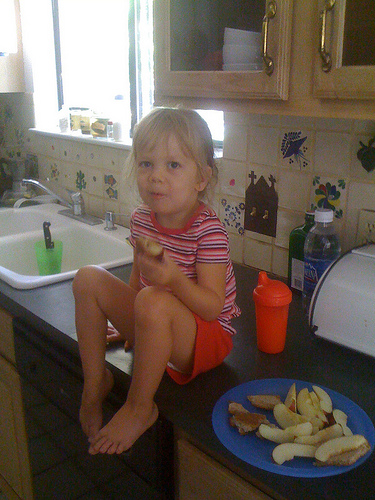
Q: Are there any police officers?
A: No, there are no police officers.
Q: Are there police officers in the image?
A: No, there are no police officers.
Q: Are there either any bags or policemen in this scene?
A: No, there are no policemen or bags.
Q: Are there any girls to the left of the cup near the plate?
A: Yes, there is a girl to the left of the cup.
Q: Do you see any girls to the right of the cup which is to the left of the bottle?
A: No, the girl is to the left of the cup.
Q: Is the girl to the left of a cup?
A: Yes, the girl is to the left of a cup.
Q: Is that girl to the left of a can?
A: No, the girl is to the left of a cup.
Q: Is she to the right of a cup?
A: No, the girl is to the left of a cup.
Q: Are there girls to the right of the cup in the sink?
A: Yes, there is a girl to the right of the cup.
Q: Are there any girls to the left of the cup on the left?
A: No, the girl is to the right of the cup.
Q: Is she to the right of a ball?
A: No, the girl is to the right of the cup.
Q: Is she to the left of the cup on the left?
A: No, the girl is to the right of the cup.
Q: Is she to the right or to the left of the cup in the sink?
A: The girl is to the right of the cup.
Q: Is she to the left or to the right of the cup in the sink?
A: The girl is to the right of the cup.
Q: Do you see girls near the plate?
A: Yes, there is a girl near the plate.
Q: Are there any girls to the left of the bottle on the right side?
A: Yes, there is a girl to the left of the bottle.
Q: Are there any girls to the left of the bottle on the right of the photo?
A: Yes, there is a girl to the left of the bottle.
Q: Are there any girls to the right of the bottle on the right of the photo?
A: No, the girl is to the left of the bottle.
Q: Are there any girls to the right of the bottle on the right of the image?
A: No, the girl is to the left of the bottle.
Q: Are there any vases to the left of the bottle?
A: No, there is a girl to the left of the bottle.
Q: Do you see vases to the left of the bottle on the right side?
A: No, there is a girl to the left of the bottle.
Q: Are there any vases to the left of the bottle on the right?
A: No, there is a girl to the left of the bottle.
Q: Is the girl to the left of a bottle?
A: Yes, the girl is to the left of a bottle.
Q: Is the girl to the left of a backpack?
A: No, the girl is to the left of a bottle.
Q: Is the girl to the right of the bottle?
A: No, the girl is to the left of the bottle.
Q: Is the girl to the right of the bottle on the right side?
A: No, the girl is to the left of the bottle.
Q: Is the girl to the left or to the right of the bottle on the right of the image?
A: The girl is to the left of the bottle.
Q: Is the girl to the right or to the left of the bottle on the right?
A: The girl is to the left of the bottle.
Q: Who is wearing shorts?
A: The girl is wearing shorts.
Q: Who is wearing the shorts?
A: The girl is wearing shorts.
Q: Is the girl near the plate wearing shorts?
A: Yes, the girl is wearing shorts.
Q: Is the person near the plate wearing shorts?
A: Yes, the girl is wearing shorts.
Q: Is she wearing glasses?
A: No, the girl is wearing shorts.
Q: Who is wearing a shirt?
A: The girl is wearing a shirt.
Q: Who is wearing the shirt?
A: The girl is wearing a shirt.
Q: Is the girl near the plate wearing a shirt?
A: Yes, the girl is wearing a shirt.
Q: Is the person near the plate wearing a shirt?
A: Yes, the girl is wearing a shirt.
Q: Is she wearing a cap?
A: No, the girl is wearing a shirt.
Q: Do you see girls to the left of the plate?
A: Yes, there is a girl to the left of the plate.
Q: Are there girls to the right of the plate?
A: No, the girl is to the left of the plate.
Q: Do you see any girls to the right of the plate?
A: No, the girl is to the left of the plate.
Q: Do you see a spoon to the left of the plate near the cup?
A: No, there is a girl to the left of the plate.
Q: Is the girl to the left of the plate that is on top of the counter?
A: Yes, the girl is to the left of the plate.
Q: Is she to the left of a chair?
A: No, the girl is to the left of the plate.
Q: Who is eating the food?
A: The girl is eating the food.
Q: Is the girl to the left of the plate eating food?
A: Yes, the girl is eating food.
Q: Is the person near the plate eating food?
A: Yes, the girl is eating food.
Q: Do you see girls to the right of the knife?
A: Yes, there is a girl to the right of the knife.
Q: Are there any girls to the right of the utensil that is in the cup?
A: Yes, there is a girl to the right of the knife.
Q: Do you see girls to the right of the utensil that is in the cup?
A: Yes, there is a girl to the right of the knife.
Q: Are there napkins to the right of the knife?
A: No, there is a girl to the right of the knife.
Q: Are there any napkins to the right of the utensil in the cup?
A: No, there is a girl to the right of the knife.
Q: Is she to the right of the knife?
A: Yes, the girl is to the right of the knife.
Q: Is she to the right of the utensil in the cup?
A: Yes, the girl is to the right of the knife.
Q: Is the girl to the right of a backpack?
A: No, the girl is to the right of the knife.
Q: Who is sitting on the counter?
A: The girl is sitting on the counter.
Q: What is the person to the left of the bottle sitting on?
A: The girl is sitting on the counter.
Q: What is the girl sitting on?
A: The girl is sitting on the counter.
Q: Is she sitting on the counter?
A: Yes, the girl is sitting on the counter.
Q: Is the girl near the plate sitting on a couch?
A: No, the girl is sitting on the counter.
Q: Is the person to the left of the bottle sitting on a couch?
A: No, the girl is sitting on the counter.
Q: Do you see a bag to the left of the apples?
A: No, there is a girl to the left of the apples.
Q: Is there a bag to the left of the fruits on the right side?
A: No, there is a girl to the left of the apples.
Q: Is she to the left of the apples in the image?
A: Yes, the girl is to the left of the apples.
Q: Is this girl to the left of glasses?
A: No, the girl is to the left of the apples.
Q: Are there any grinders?
A: No, there are no grinders.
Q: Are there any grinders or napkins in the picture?
A: No, there are no grinders or napkins.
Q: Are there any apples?
A: Yes, there are apples.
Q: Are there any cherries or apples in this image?
A: Yes, there are apples.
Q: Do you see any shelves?
A: No, there are no shelves.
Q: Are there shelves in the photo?
A: No, there are no shelves.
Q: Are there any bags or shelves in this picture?
A: No, there are no shelves or bags.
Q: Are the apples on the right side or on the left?
A: The apples are on the right of the image.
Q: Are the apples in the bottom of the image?
A: Yes, the apples are in the bottom of the image.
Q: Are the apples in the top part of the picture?
A: No, the apples are in the bottom of the image.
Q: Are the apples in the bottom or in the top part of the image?
A: The apples are in the bottom of the image.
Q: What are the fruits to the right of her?
A: The fruits are apples.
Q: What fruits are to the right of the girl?
A: The fruits are apples.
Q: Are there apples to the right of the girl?
A: Yes, there are apples to the right of the girl.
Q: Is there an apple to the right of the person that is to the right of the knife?
A: Yes, there are apples to the right of the girl.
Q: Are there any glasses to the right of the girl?
A: No, there are apples to the right of the girl.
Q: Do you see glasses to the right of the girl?
A: No, there are apples to the right of the girl.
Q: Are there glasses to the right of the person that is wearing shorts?
A: No, there are apples to the right of the girl.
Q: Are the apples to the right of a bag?
A: No, the apples are to the right of the girl.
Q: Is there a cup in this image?
A: Yes, there is a cup.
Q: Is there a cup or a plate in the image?
A: Yes, there is a cup.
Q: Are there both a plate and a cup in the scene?
A: Yes, there are both a cup and a plate.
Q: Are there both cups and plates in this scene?
A: Yes, there are both a cup and a plate.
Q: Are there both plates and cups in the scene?
A: Yes, there are both a cup and a plate.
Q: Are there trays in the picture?
A: No, there are no trays.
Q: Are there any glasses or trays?
A: No, there are no trays or glasses.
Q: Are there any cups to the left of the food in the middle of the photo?
A: Yes, there is a cup to the left of the food.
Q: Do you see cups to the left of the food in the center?
A: Yes, there is a cup to the left of the food.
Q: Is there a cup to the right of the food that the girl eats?
A: No, the cup is to the left of the food.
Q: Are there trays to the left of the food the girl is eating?
A: No, there is a cup to the left of the food.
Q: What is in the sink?
A: The cup is in the sink.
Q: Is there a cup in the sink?
A: Yes, there is a cup in the sink.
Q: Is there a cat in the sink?
A: No, there is a cup in the sink.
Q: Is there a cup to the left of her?
A: Yes, there is a cup to the left of the girl.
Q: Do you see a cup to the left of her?
A: Yes, there is a cup to the left of the girl.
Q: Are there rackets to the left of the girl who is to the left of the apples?
A: No, there is a cup to the left of the girl.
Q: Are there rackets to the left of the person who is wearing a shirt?
A: No, there is a cup to the left of the girl.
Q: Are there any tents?
A: No, there are no tents.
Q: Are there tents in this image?
A: No, there are no tents.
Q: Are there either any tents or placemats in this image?
A: No, there are no tents or placemats.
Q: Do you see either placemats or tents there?
A: No, there are no tents or placemats.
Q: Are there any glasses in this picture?
A: No, there are no glasses.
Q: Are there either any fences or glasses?
A: No, there are no glasses or fences.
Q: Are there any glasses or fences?
A: No, there are no glasses or fences.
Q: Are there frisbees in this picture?
A: No, there are no frisbees.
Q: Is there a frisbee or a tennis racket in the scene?
A: No, there are no frisbees or rackets.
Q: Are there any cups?
A: Yes, there is a cup.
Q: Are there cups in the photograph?
A: Yes, there is a cup.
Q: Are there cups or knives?
A: Yes, there is a cup.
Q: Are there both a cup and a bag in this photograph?
A: No, there is a cup but no bags.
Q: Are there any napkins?
A: No, there are no napkins.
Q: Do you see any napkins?
A: No, there are no napkins.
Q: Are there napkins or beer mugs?
A: No, there are no napkins or beer mugs.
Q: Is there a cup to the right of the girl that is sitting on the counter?
A: Yes, there is a cup to the right of the girl.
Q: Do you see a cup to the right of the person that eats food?
A: Yes, there is a cup to the right of the girl.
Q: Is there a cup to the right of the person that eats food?
A: Yes, there is a cup to the right of the girl.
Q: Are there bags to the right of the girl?
A: No, there is a cup to the right of the girl.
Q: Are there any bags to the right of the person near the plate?
A: No, there is a cup to the right of the girl.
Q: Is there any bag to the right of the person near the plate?
A: No, there is a cup to the right of the girl.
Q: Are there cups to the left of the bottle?
A: Yes, there is a cup to the left of the bottle.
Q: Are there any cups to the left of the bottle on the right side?
A: Yes, there is a cup to the left of the bottle.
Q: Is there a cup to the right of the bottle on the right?
A: No, the cup is to the left of the bottle.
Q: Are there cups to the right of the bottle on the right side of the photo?
A: No, the cup is to the left of the bottle.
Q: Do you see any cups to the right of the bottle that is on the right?
A: No, the cup is to the left of the bottle.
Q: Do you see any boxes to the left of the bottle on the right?
A: No, there is a cup to the left of the bottle.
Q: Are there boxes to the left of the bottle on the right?
A: No, there is a cup to the left of the bottle.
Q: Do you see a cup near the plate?
A: Yes, there is a cup near the plate.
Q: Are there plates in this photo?
A: Yes, there is a plate.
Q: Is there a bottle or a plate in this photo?
A: Yes, there is a plate.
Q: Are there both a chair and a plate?
A: No, there is a plate but no chairs.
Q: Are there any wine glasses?
A: No, there are no wine glasses.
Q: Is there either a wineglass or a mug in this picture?
A: No, there are no wine glasses or mugs.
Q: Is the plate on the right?
A: Yes, the plate is on the right of the image.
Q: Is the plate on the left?
A: No, the plate is on the right of the image.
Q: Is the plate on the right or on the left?
A: The plate is on the right of the image.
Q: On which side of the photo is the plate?
A: The plate is on the right of the image.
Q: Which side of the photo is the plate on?
A: The plate is on the right of the image.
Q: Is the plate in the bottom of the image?
A: Yes, the plate is in the bottom of the image.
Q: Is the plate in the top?
A: No, the plate is in the bottom of the image.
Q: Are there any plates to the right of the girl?
A: Yes, there is a plate to the right of the girl.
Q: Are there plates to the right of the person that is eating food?
A: Yes, there is a plate to the right of the girl.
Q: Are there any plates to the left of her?
A: No, the plate is to the right of the girl.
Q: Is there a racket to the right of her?
A: No, there is a plate to the right of the girl.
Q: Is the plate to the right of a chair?
A: No, the plate is to the right of the girl.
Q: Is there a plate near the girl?
A: Yes, there is a plate near the girl.